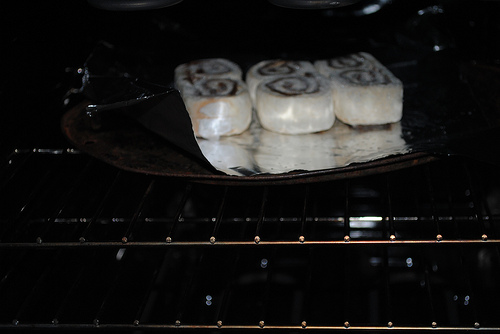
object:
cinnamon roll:
[316, 54, 379, 97]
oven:
[1, 1, 499, 332]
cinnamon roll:
[176, 81, 252, 135]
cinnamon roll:
[249, 59, 311, 106]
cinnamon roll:
[176, 59, 244, 97]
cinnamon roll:
[330, 68, 405, 126]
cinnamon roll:
[253, 80, 335, 134]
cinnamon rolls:
[170, 52, 408, 141]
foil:
[177, 61, 423, 177]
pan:
[61, 51, 493, 185]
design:
[198, 62, 233, 77]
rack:
[10, 148, 499, 287]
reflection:
[192, 133, 432, 179]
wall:
[1, 1, 26, 332]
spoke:
[2, 238, 17, 250]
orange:
[195, 100, 238, 137]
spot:
[337, 199, 390, 235]